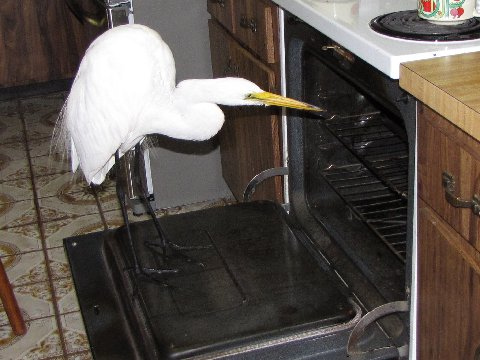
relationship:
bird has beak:
[50, 24, 324, 299] [251, 91, 323, 112]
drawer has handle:
[205, 0, 274, 60] [238, 18, 256, 32]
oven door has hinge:
[65, 196, 396, 357] [348, 300, 411, 360]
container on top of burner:
[419, 0, 479, 28] [370, 13, 480, 39]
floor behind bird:
[1, 86, 236, 359] [50, 24, 324, 299]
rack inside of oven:
[323, 109, 410, 203] [286, 19, 416, 351]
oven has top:
[286, 19, 416, 351] [273, 1, 478, 81]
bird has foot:
[50, 24, 324, 299] [144, 238, 210, 275]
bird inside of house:
[50, 24, 324, 299] [1, 2, 478, 360]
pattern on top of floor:
[5, 163, 70, 192] [1, 86, 236, 359]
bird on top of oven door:
[50, 24, 324, 299] [65, 196, 396, 357]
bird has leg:
[50, 24, 324, 299] [135, 142, 167, 244]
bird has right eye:
[50, 24, 324, 299] [245, 93, 253, 100]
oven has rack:
[286, 19, 416, 351] [323, 109, 410, 203]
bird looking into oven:
[50, 24, 324, 299] [286, 19, 416, 351]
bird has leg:
[50, 24, 324, 299] [116, 149, 140, 272]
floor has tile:
[1, 86, 236, 359] [38, 191, 100, 221]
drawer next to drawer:
[205, 0, 274, 60] [206, 0, 236, 37]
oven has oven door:
[286, 19, 416, 351] [65, 196, 396, 357]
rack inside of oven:
[322, 156, 408, 265] [286, 19, 416, 351]